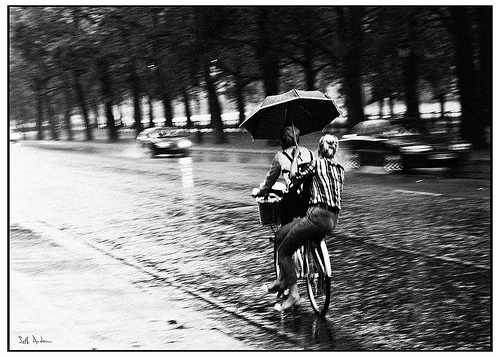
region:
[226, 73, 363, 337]
Two people riding a bicycke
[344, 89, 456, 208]
CAr on the pavement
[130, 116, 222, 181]
CAr on the pavement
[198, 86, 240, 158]
Large wooden tree trunk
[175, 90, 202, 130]
Large wooden tree trunk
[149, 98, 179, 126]
Large wooden tree trunk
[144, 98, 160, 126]
Large wooden tree trunk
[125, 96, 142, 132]
Large wooden tree trunk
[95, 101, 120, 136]
Large wooden tree trunk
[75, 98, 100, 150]
Large wooden tree trunk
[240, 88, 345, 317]
Woman in back of bike holding umbrella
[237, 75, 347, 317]
Two people riding bike down street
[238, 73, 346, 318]
Two people riding bike in the rain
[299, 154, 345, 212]
Women's plaid long sleeve shirt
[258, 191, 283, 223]
Basket on front of bike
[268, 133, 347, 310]
Woman in back of bike dangling legs off side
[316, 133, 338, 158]
Woman's hair in bun on back of head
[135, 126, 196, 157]
Car driving in the rain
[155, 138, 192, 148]
Lit headlights on front of car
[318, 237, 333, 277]
Chrome fender on back of bike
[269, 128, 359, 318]
two people riding in rain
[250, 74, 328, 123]
woman holding dark umbrella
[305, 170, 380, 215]
woman wearing plaid shir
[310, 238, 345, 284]
shiny fender on bike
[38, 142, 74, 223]
street is shiny and wet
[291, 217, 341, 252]
woman wearing dark pants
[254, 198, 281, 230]
basket on bikes front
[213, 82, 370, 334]
Two people on the bike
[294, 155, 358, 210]
woman wearing black and white shirt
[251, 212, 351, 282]
woman wearing gray pants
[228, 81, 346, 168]
woman holding a umbrella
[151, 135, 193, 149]
head lights on a car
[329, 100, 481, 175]
car driving in the rain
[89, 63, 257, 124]
trees next to the road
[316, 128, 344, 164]
woman with blond hair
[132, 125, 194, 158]
the car is splashing water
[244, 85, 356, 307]
two people are riding a bicycle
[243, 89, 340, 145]
the umbrell is black in color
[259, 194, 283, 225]
a basket is on the bicycle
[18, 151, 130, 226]
white light reflection on wet street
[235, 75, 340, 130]
open umbrella guarding against rain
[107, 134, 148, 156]
water wash from car tire passing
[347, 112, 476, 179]
small black passenger vehicle blurred from speed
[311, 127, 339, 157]
blonde hair tied back in tight ponytail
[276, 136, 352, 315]
woman sitting on back bike frame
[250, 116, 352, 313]
two people riding one bike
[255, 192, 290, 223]
front picnic style basket on front of bike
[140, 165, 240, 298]
rivulets of rippling water on black asphalt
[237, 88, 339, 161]
open black umbrella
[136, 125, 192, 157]
dark colored sedan style car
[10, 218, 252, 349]
poured concrete sidewalk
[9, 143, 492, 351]
black water covered asphalt road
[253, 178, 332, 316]
light colored bicycle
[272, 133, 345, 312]
woman on the back of a bike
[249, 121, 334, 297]
person riding on a bicycle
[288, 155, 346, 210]
black and white plaid shirt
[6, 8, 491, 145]
line of trees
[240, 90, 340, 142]
the umbrella is wide open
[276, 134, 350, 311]
a woman is on a bicycle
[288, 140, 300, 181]
the woman is holding a bicycle